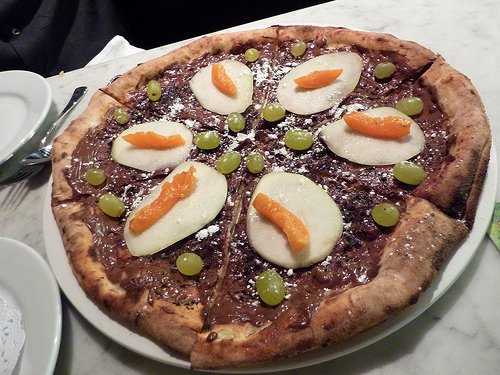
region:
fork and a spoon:
[0, 84, 87, 186]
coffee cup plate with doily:
[0, 233, 64, 373]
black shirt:
[0, 0, 129, 77]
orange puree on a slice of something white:
[107, 50, 424, 271]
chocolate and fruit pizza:
[48, 22, 492, 373]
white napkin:
[83, 33, 148, 68]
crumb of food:
[57, 68, 65, 78]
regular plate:
[0, 67, 54, 169]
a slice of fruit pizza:
[187, 139, 469, 371]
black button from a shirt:
[10, 25, 22, 38]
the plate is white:
[47, 87, 441, 369]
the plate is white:
[157, 150, 354, 364]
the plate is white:
[200, 191, 435, 366]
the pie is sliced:
[70, 56, 464, 333]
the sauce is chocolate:
[208, 160, 381, 330]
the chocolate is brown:
[209, 180, 407, 352]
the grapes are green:
[180, 91, 324, 189]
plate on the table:
[4, 60, 84, 331]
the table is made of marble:
[218, 8, 420, 65]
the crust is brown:
[185, 292, 405, 366]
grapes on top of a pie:
[166, 110, 348, 220]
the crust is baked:
[50, 202, 200, 373]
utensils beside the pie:
[5, 74, 125, 223]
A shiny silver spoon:
[12, 75, 108, 190]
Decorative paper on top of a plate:
[1, 265, 27, 370]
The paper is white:
[1, 295, 41, 366]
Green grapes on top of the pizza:
[81, 35, 452, 320]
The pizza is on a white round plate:
[47, 40, 469, 348]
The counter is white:
[345, 10, 486, 86]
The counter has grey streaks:
[360, 7, 485, 92]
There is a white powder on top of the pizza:
[107, 23, 418, 325]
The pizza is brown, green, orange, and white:
[60, 26, 455, 331]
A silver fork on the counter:
[3, 77, 100, 197]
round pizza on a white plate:
[93, 36, 463, 356]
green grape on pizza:
[250, 267, 288, 312]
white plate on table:
[1, 65, 60, 132]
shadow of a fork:
[0, 177, 35, 209]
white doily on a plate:
[0, 290, 30, 373]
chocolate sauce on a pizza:
[60, 121, 117, 192]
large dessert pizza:
[88, 14, 498, 344]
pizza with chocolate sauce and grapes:
[82, 47, 440, 349]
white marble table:
[356, 1, 497, 51]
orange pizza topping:
[237, 185, 311, 262]